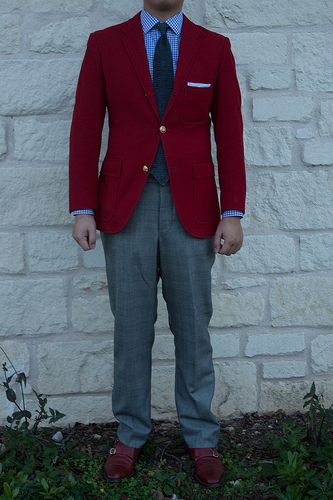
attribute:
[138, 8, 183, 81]
shirt — blue, white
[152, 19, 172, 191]
tie — blue, gray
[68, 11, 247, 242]
coat — red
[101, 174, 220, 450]
pants — gray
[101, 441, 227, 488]
shoes — brown, red, leather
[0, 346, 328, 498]
vegetation — green, dark green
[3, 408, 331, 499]
ground — rocky soil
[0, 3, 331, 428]
wall — gray, stone, white, rock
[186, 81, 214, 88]
card — white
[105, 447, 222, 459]
buckles — silver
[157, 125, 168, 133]
button — gold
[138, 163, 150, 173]
button — gold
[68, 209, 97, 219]
cuff — blue, white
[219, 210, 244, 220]
cuff — blue, white